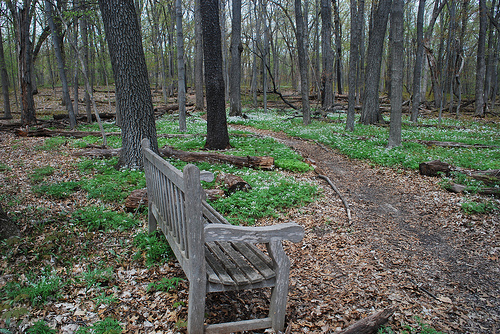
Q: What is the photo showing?
A: It is showing a forest.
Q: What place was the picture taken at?
A: It was taken at the forest.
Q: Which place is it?
A: It is a forest.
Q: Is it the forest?
A: Yes, it is the forest.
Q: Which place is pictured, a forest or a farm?
A: It is a forest.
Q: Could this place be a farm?
A: No, it is a forest.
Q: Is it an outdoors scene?
A: Yes, it is outdoors.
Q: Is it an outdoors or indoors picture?
A: It is outdoors.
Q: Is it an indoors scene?
A: No, it is outdoors.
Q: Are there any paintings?
A: No, there are no paintings.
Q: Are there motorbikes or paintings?
A: No, there are no paintings or motorbikes.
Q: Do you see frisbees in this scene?
A: No, there are no frisbees.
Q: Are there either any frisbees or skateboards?
A: No, there are no frisbees or skateboards.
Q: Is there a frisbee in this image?
A: No, there are no frisbees.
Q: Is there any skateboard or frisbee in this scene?
A: No, there are no frisbees or skateboards.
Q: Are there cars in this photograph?
A: No, there are no cars.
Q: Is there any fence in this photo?
A: Yes, there is a fence.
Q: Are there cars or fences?
A: Yes, there is a fence.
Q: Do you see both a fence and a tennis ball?
A: No, there is a fence but no tennis balls.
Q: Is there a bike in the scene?
A: No, there are no bikes.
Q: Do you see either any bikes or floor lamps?
A: No, there are no bikes or floor lamps.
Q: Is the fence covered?
A: Yes, the fence is covered.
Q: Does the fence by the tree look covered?
A: Yes, the fence is covered.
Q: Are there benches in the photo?
A: Yes, there is a bench.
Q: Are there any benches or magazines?
A: Yes, there is a bench.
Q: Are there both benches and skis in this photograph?
A: No, there is a bench but no skis.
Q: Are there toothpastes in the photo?
A: No, there are no toothpastes.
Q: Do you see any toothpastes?
A: No, there are no toothpastes.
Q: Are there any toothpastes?
A: No, there are no toothpastes.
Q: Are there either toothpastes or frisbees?
A: No, there are no toothpastes or frisbees.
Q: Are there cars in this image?
A: No, there are no cars.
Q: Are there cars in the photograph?
A: No, there are no cars.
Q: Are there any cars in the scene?
A: No, there are no cars.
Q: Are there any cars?
A: No, there are no cars.